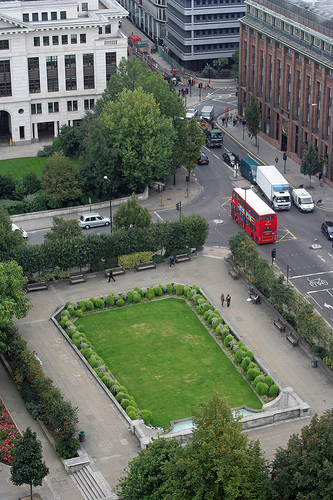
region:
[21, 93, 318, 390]
this is an urban setting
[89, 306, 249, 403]
there is a lawn here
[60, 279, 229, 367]
there are green bushes around the lawn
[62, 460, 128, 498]
these are steps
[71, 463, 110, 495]
the steps are made of cement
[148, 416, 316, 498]
these trees are very tall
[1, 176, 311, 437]
this is an aerial view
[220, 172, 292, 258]
this is a double decker bus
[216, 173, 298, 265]
the bus is red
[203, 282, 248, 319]
these are two people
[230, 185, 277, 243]
a red double decker bus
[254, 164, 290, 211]
a white commercial truck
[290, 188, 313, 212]
a white commercial truck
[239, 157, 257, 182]
a blue commercial truck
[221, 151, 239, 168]
a black car in street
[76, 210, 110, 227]
a silver car in street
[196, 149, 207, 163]
a black car in street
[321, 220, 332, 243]
a black car in street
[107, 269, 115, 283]
a pedestrian on sidewalk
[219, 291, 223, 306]
a pedestrian on sidewalk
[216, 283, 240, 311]
People walking on the pavement.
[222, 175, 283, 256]
A red double decker bus.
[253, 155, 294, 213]
A white semi trick.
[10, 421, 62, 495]
Trees in a small park.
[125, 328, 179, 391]
Grass in a small park.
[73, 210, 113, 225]
A silver car on the street.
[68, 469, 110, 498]
Stairs in a small park.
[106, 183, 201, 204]
The cemented sidewalk.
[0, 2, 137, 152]
A large white building.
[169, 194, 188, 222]
A stoplight in the street.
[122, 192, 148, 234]
this is a tree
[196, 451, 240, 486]
the leaves are green in color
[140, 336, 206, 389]
this is a grass area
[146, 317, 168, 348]
the grass is green in color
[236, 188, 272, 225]
this is a bus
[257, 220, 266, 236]
the bus is red in color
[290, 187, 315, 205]
this is a van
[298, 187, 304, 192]
the van is white in color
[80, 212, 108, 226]
this is a car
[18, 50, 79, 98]
this is a wall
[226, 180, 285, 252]
red double decker tour bus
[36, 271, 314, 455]
court yard with green grass in center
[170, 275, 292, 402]
row of decorative shrubs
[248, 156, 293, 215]
white delivery truck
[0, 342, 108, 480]
row of trees in park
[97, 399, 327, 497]
row of large trees alongside park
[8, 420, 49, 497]
single tree with cement flooring nearby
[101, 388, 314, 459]
cement decorative fence for park boundary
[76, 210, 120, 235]
silver mini van on street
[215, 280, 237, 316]
two people walking in park